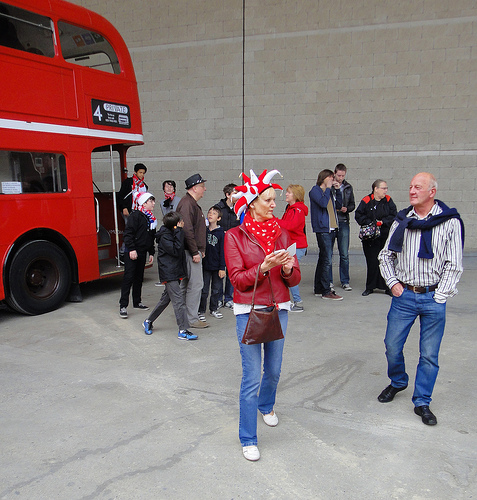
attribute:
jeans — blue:
[385, 286, 446, 403]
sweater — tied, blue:
[394, 199, 465, 254]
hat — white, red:
[228, 170, 285, 221]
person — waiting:
[358, 180, 397, 294]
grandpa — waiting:
[176, 174, 212, 331]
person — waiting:
[122, 193, 157, 321]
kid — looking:
[198, 208, 223, 321]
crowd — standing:
[117, 165, 464, 464]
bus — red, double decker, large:
[3, 0, 145, 317]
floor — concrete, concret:
[0, 253, 477, 499]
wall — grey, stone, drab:
[73, 1, 476, 247]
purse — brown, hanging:
[245, 267, 284, 348]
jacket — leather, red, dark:
[224, 224, 300, 305]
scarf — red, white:
[246, 213, 282, 257]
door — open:
[88, 140, 141, 275]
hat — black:
[184, 174, 206, 188]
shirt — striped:
[379, 205, 460, 303]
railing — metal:
[90, 198, 102, 232]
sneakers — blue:
[140, 320, 198, 341]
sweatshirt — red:
[281, 201, 309, 250]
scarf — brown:
[328, 190, 338, 229]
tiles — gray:
[238, 31, 476, 158]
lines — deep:
[237, 0, 250, 184]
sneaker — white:
[242, 448, 260, 464]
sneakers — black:
[120, 301, 150, 321]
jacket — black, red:
[356, 183, 397, 242]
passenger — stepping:
[116, 159, 150, 266]